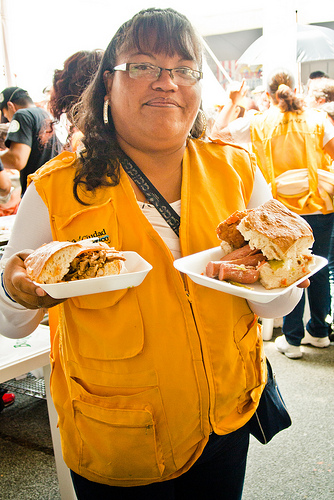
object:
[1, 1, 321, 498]
person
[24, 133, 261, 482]
shirt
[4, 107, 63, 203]
shirt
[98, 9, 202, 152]
head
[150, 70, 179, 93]
nose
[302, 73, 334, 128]
person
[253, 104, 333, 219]
shirt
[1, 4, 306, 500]
woman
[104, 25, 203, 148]
face